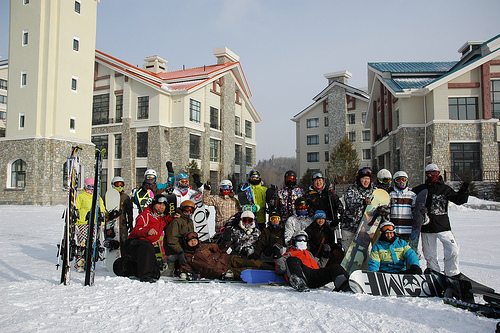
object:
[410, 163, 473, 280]
guy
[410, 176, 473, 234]
jacket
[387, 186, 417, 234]
shirt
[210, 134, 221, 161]
window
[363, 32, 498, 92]
roof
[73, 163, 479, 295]
group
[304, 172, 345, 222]
person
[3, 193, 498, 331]
snow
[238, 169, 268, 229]
people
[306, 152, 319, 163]
window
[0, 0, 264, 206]
building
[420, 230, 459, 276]
pants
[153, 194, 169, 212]
head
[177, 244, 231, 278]
coat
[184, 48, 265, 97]
roof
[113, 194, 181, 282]
guy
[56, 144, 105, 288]
ski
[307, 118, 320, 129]
window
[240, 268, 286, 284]
snowboard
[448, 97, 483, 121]
window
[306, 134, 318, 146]
window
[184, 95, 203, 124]
window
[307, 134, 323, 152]
window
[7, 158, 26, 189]
window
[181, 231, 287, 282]
guy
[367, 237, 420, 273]
coat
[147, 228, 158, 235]
hand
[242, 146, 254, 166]
window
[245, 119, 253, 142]
window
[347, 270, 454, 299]
snowboard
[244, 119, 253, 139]
window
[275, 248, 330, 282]
jacket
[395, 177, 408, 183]
goggles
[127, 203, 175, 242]
snow suit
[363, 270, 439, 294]
writing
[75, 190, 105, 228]
coat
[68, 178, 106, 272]
person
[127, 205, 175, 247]
coat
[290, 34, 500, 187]
building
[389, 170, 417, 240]
guy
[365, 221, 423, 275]
guy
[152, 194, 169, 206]
hat